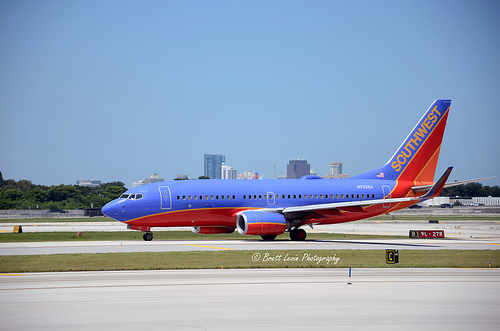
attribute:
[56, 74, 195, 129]
clouds — white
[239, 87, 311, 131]
clouds — white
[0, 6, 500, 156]
sky — blue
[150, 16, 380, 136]
sky — blue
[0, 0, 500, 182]
sky — blue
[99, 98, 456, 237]
plane — multi colored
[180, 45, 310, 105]
sky — blue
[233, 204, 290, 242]
plane engine — large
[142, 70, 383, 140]
clouds — white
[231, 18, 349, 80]
sky — blue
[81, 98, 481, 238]
plane — Southwest, airlines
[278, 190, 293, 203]
windows — small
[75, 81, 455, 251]
plane — blue, red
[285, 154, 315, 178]
building — tall, brown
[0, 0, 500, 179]
clouds — white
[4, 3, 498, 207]
sky — blue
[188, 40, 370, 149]
sky — blue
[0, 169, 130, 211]
trees — variety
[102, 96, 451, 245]
jet — orange, blue, red, passenger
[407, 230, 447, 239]
red sign — large